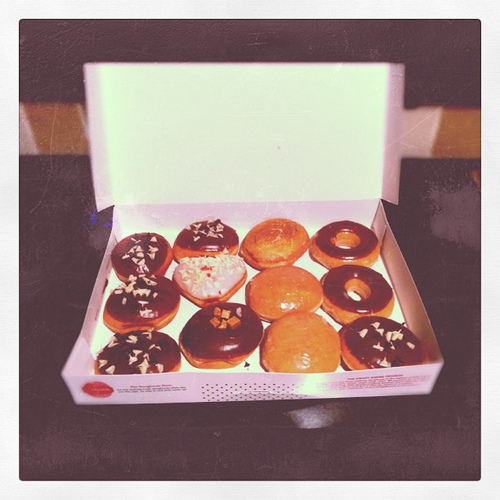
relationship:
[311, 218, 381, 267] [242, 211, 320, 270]
donut next to donut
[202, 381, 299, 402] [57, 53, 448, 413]
dots on box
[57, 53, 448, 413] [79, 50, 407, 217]
box has lid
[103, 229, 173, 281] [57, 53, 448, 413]
donut in box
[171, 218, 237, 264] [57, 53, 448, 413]
donut in box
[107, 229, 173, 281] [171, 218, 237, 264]
donut beside donut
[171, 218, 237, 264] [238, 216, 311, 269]
donut beside donut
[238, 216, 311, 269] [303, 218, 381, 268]
donut beside donut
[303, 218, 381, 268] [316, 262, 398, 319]
donut beside donut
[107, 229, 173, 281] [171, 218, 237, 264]
donut next to donut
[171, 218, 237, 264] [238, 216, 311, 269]
donut next to donut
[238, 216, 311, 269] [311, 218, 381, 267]
donut next to donut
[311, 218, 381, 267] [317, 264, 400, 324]
donut next to donut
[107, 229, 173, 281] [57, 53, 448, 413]
donut in box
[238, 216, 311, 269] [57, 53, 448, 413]
donut in box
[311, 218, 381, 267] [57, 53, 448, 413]
donut in box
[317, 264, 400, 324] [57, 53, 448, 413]
donut in box